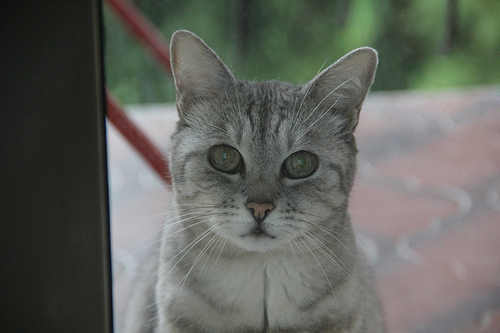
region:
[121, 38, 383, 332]
gray and white cat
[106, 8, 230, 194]
red rails behind cat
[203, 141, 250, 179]
little yellow left eye of cat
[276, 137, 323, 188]
little yellow right eye of cat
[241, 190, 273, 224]
little pinky nose of cat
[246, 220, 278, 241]
little black mouth of cat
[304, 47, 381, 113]
gray flurry right ear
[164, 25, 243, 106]
gray furry left ear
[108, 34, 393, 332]
beautifull cat with eyes wide open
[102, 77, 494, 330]
bricked floor where cat is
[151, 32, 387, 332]
Cat in front of the camera.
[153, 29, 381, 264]
The cat is looking at the camera.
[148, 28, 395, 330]
The cat is grey.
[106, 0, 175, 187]
The poles are red.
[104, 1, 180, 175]
The poles are angled.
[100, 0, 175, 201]
There are two poles.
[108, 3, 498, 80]
Trees and grass in the background.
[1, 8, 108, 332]
The wall is brown.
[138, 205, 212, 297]
The whiskers are white.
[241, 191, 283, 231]
The nose is pink.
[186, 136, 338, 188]
eye of the cat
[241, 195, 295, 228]
nose of the cat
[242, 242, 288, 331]
a black line in cat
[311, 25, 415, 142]
ear of the cat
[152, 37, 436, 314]
face of the cat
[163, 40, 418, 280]
a small cat looking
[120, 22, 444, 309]
a cute cat looking innocent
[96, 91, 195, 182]
a red rod iron stand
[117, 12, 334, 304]
a small red rod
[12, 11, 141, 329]
a part of door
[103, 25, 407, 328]
a white cat with gray stripes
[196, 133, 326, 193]
eyes of cat are round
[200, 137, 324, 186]
eyes of cat are color green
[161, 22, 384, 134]
pointy ears of cat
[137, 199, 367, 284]
the cat has whiskers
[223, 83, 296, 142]
gray stripe on cat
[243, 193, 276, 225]
nose of cat is color pink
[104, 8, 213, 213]
two red rods behind a cat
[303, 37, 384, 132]
right ear of cat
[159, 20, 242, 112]
left ear of cat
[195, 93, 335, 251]
A cat on its haunches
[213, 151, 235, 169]
The right eye of the cat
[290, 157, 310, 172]
The cat's left eye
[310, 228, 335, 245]
Left whiskers on the cat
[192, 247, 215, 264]
The cat's right whiskers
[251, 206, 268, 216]
The cat's nose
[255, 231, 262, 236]
The cat's mouth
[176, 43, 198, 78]
The right ear standing upright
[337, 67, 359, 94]
The inside of the left ear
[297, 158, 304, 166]
The eye reflecting light